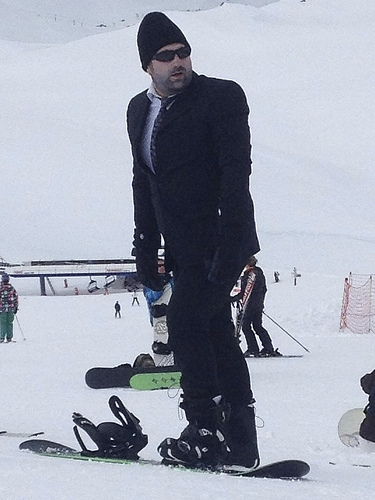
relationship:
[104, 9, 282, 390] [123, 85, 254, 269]
man wearing suit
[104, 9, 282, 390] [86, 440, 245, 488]
man stepping on snowboard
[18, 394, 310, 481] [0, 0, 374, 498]
snowboard on snow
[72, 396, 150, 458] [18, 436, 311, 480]
black binding on snowboard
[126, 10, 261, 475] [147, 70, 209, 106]
man has neck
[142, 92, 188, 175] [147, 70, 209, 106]
tie on neck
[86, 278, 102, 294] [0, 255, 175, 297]
empty chair on chairlift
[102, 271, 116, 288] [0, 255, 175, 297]
empty chair on chairlift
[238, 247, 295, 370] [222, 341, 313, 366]
man on skis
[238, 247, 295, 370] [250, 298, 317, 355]
man holding ski pole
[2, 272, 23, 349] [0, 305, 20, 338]
person wearing pants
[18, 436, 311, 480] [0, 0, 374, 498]
snowboard on snow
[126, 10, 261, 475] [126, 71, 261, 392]
man wearing suit